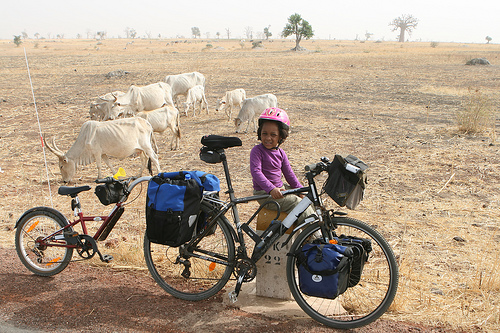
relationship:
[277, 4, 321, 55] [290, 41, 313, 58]
tree with trunk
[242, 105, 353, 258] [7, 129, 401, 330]
girl sitting by bike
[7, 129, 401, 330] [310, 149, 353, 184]
bike with handle bars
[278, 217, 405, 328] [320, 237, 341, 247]
tire with reflector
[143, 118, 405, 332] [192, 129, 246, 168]
bicycle with seat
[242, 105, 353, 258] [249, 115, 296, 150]
girl has head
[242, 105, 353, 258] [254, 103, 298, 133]
girl wearing helmet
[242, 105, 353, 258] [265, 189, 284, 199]
girl has hand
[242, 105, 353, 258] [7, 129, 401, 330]
girl near bike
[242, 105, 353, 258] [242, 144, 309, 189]
girl with shirt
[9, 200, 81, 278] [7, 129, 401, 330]
wheel on bike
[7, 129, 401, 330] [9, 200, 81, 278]
bike with wheel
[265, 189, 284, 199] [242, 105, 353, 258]
hand of girl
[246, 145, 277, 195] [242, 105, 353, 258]
arm of girl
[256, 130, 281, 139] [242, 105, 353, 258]
eyes of girl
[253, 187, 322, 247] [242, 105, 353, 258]
leg of girl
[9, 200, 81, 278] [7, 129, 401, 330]
wheel of bike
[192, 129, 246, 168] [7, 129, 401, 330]
seat of bike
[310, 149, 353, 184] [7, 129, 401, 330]
handle bars on bike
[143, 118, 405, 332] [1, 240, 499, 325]
bicycle on dirt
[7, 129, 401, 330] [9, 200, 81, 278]
bike has wheel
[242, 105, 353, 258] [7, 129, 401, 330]
girl on bike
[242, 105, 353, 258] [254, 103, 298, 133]
girl with helmet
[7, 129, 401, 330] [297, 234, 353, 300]
bike has bag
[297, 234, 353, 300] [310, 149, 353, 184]
bag on handle bars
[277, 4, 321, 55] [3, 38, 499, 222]
tree in plain